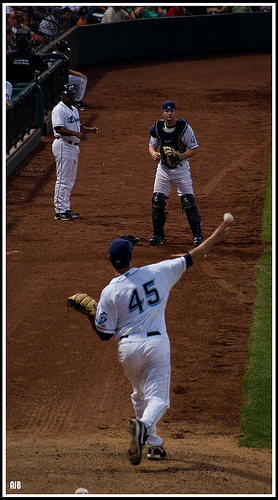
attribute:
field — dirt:
[6, 52, 270, 497]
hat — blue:
[106, 238, 129, 269]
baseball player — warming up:
[63, 205, 236, 460]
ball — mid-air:
[218, 205, 244, 233]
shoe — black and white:
[53, 212, 73, 220]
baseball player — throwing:
[87, 215, 232, 462]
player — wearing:
[51, 83, 97, 220]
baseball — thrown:
[220, 212, 233, 227]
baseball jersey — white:
[90, 254, 192, 342]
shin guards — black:
[177, 191, 205, 239]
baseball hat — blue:
[107, 238, 134, 264]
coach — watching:
[44, 77, 99, 225]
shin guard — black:
[146, 191, 168, 239]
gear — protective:
[142, 120, 197, 162]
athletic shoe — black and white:
[55, 211, 71, 222]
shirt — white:
[87, 259, 185, 343]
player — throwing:
[88, 212, 230, 466]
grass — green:
[256, 295, 267, 414]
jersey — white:
[88, 254, 192, 446]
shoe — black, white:
[125, 418, 148, 465]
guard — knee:
[149, 190, 166, 235]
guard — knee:
[178, 193, 204, 236]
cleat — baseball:
[126, 417, 146, 466]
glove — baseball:
[160, 144, 180, 169]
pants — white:
[114, 340, 188, 427]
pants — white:
[108, 331, 196, 415]